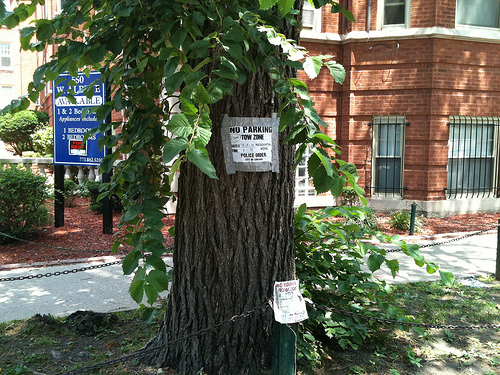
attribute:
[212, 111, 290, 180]
sign — white, duct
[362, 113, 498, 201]
window — fenced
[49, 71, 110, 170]
sign — blue, white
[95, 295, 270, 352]
chain — long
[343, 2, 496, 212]
build — brick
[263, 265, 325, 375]
low — lower